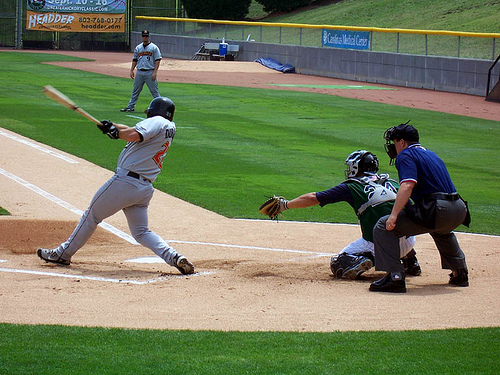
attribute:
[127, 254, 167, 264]
plate — home plate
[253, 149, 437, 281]
catcher — preparing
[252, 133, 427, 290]
catcher — baseball, glove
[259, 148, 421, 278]
catcher — extending